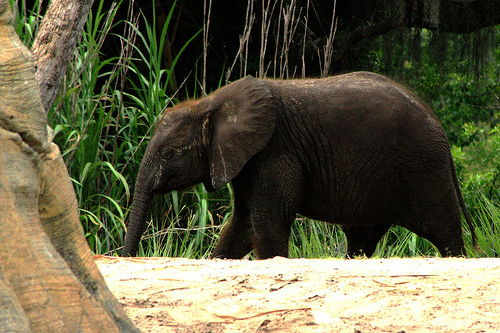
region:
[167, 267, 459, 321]
The ground is the color beige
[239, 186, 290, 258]
The leg of the elephant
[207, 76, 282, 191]
The ear of the elephant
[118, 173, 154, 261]
The trunk of the elephant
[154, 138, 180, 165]
The eye of the elephant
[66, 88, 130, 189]
The grass is tall and green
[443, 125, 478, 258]
The tail of the elephant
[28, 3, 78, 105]
The tree trunk is brown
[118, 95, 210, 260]
The head of the elephant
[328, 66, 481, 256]
The end of the elephant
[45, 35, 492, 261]
the elephant is walking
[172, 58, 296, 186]
the ear is big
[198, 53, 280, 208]
the ear is flat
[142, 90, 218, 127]
the hair on the head is brown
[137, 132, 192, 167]
the eye is small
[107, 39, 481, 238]
the elephant is brown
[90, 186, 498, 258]
the grass is high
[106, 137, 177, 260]
the trunk is long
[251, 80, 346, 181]
the skin is wrinkled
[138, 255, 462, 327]
the dirt is tan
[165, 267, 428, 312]
The color of ground is brown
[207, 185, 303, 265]
The front legs of the elephant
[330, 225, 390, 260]
The back leg of the elephant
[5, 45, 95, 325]
The tree trunk is the color brown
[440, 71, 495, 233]
The grass is tall and green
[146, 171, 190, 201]
The mouth of the elephant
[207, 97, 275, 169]
Elephant has large gray ear.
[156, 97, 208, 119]
Elephant has fuzzy brown hair on head.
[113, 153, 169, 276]
Elephant has long gray trunk.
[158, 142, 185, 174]
Elephant has dark eye.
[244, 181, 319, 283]
Elephant has gray leg.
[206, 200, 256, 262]
Elephant has gray leg.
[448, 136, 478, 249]
Elephant has gray tail.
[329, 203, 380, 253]
Elephant has gray leg.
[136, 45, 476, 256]
Large gray elephant standing in grassy area.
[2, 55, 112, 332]
Large tree trunk near elephant.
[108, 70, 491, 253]
a single elephant walks by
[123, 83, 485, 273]
the elephant doesnt look full grown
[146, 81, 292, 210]
the elephant appears to have scars on him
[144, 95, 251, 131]
the elephant has fuzzy hair on his head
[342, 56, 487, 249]
the elephant appears to have fuzzy hair on his butt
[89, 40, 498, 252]
the elephant is dark brown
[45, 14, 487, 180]
the elephant appears to be walking thru a jungle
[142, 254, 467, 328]
this appears to be a fallen log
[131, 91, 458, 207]
the elephant has some wrinkles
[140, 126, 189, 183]
the elephant has very small eyes for his size